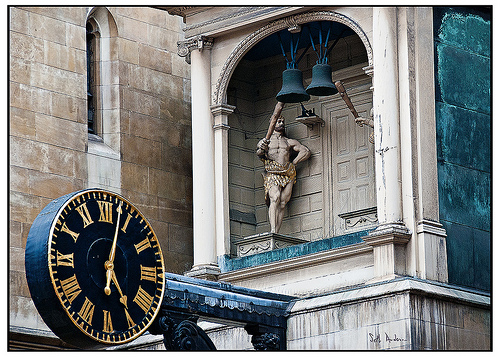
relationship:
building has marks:
[10, 9, 490, 351] [431, 6, 492, 169]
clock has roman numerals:
[25, 187, 165, 346] [56, 200, 156, 335]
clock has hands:
[25, 187, 165, 346] [104, 200, 129, 307]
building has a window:
[10, 9, 490, 351] [82, 17, 103, 143]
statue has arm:
[255, 100, 312, 233] [287, 139, 311, 167]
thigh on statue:
[266, 184, 281, 200] [255, 100, 312, 233]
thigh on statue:
[280, 185, 293, 203] [255, 100, 312, 233]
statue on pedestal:
[255, 100, 312, 233] [234, 232, 309, 259]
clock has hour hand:
[25, 187, 165, 346] [106, 261, 129, 309]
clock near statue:
[25, 187, 165, 346] [255, 100, 312, 233]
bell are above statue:
[276, 69, 311, 103] [255, 100, 312, 233]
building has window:
[10, 9, 490, 351] [82, 17, 103, 143]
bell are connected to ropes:
[276, 69, 311, 103] [280, 26, 349, 67]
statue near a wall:
[255, 100, 312, 233] [228, 32, 377, 257]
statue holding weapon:
[255, 100, 312, 233] [260, 101, 285, 158]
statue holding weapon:
[334, 78, 374, 145] [335, 78, 362, 129]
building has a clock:
[10, 9, 490, 351] [25, 187, 165, 346]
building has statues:
[10, 9, 490, 351] [256, 79, 375, 235]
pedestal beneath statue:
[234, 232, 309, 259] [255, 100, 312, 233]